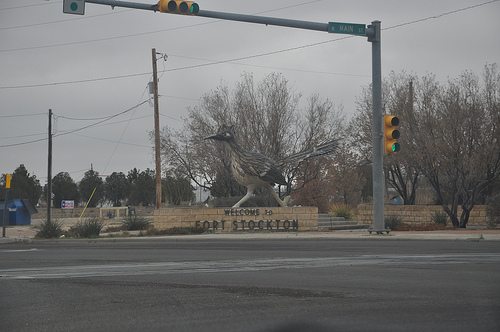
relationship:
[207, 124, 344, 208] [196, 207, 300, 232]
statue above letters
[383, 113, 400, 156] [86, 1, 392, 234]
street light on pole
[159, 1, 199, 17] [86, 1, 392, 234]
street light on pole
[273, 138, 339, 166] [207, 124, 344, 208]
tail on statue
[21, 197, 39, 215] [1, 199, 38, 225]
lid on dumpster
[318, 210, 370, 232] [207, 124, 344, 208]
stairs near statue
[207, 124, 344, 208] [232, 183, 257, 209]
statue has a leg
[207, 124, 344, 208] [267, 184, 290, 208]
statue has a leg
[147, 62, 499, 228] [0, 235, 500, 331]
trees near main street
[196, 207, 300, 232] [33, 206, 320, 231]
letters on wall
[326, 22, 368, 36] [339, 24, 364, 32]
sign says main street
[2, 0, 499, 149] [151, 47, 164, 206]
electrical lines suspend from light pole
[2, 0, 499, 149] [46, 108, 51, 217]
electrical lines suspend from light pole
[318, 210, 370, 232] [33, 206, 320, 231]
stairs by wall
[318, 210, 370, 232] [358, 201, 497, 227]
stairs by wall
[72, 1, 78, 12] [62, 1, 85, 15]
circle on sign